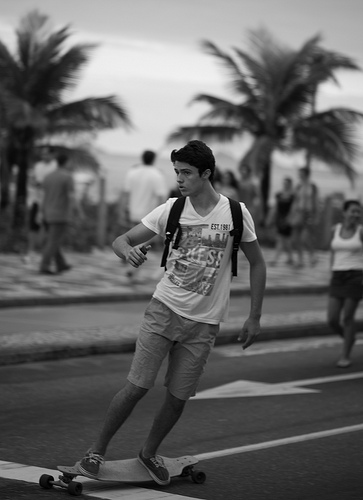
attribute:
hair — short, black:
[168, 136, 224, 184]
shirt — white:
[141, 192, 257, 324]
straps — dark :
[159, 194, 245, 278]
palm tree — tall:
[166, 22, 362, 184]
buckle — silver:
[232, 244, 240, 251]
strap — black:
[220, 184, 254, 275]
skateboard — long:
[42, 450, 216, 482]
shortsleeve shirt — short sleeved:
[139, 194, 257, 327]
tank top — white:
[325, 222, 360, 274]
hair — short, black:
[165, 140, 215, 183]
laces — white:
[86, 451, 103, 465]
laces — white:
[148, 453, 164, 469]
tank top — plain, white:
[328, 222, 362, 273]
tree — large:
[190, 24, 355, 240]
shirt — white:
[330, 222, 351, 271]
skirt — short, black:
[329, 267, 350, 300]